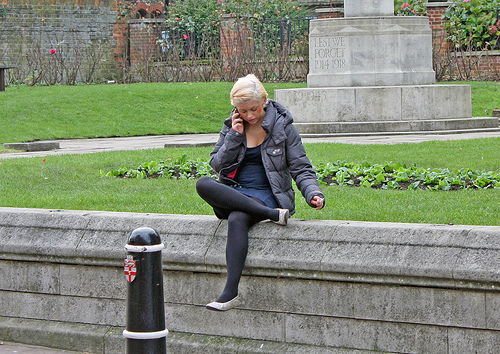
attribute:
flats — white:
[178, 283, 280, 330]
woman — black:
[198, 75, 327, 316]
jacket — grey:
[202, 110, 347, 218]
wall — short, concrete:
[3, 209, 497, 352]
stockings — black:
[193, 176, 285, 312]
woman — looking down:
[215, 75, 308, 243]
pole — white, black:
[116, 222, 173, 352]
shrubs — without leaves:
[8, 15, 315, 80]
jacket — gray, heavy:
[199, 100, 326, 212]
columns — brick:
[118, 20, 145, 75]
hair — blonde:
[228, 70, 268, 110]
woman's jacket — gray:
[196, 101, 397, 207]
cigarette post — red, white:
[121, 225, 167, 352]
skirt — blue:
[230, 180, 280, 212]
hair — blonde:
[226, 70, 261, 99]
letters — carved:
[306, 37, 349, 77]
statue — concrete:
[250, 1, 467, 122]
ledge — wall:
[6, 203, 484, 289]